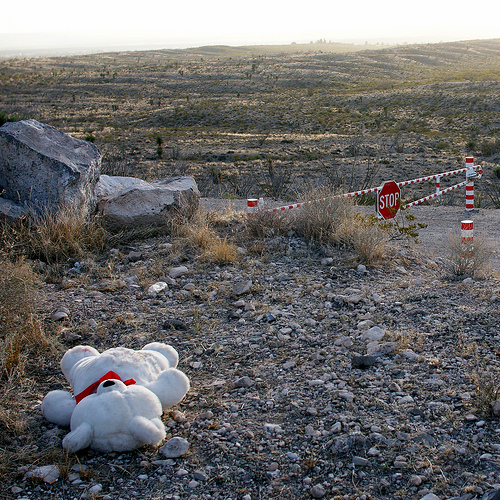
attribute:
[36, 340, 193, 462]
teddy bear — white, laying, sleeping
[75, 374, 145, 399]
ribbon — red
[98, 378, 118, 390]
nose — black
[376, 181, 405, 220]
sign — white, red, stop sign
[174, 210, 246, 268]
grass — dead, yellow, patch, brown, dry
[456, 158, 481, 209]
pole — white, red, orange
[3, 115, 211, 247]
boulder — gray, huge, beige, small, large, big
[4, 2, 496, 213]
mountains — dusty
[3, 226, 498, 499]
ground — gravel, rocks, rocky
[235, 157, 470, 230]
gate — barrier, white, red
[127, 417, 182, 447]
ear — big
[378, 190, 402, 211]
letters — white